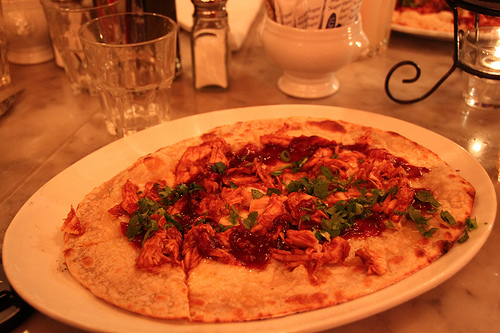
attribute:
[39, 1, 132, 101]
glass — clear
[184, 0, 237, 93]
salt — white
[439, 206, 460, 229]
vegetable — green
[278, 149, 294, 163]
vegetable — green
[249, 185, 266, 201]
vegetable — green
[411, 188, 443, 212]
vegetable — green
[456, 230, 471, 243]
vegetable — green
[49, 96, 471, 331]
pizza — pictured, red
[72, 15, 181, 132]
glass — empty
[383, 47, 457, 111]
frame — metallic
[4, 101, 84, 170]
table — pictured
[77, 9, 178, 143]
glass — drinking glass, clear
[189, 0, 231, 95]
shaker — salt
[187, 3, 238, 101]
salt shaker — glass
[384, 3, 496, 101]
metallic — black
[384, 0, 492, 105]
candle holder — black, metal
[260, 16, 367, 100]
cup — white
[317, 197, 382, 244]
herb — fresh, green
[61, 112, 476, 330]
pizza — cut, small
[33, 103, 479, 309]
flatbread — pictured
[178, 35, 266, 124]
salt shaker — pictured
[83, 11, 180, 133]
glass — pictured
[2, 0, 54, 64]
cup — small, white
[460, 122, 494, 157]
reflection — light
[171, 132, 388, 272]
sauce — red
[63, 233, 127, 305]
tan color — pictured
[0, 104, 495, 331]
plate — white, small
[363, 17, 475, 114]
wire. — pictured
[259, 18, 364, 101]
holder — white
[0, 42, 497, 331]
table — grey, pictured